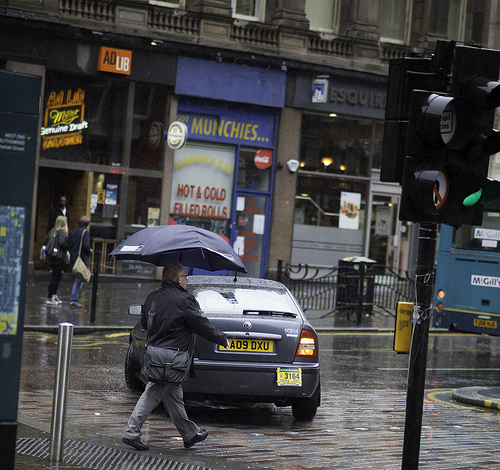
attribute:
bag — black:
[139, 340, 192, 385]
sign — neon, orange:
[40, 81, 88, 154]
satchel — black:
[138, 294, 195, 386]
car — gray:
[122, 273, 322, 423]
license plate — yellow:
[212, 336, 274, 353]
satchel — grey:
[135, 339, 195, 389]